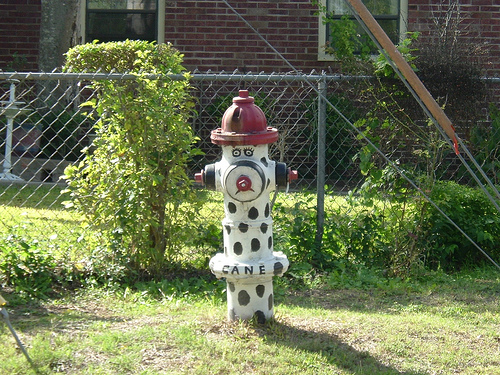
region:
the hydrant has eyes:
[225, 144, 259, 159]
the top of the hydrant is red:
[200, 89, 282, 147]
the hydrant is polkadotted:
[184, 87, 311, 322]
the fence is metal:
[12, 55, 66, 205]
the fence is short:
[7, 49, 82, 225]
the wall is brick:
[181, 25, 241, 59]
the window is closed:
[85, 3, 166, 41]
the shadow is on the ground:
[315, 322, 367, 371]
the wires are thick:
[437, 60, 496, 277]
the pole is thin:
[302, 135, 340, 268]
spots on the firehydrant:
[214, 202, 277, 292]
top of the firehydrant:
[193, 90, 280, 154]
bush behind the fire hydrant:
[30, 87, 203, 309]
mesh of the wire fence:
[273, 101, 309, 174]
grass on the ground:
[96, 323, 203, 368]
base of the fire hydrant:
[205, 287, 293, 342]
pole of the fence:
[290, 95, 340, 264]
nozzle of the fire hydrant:
[265, 157, 305, 225]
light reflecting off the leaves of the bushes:
[26, 207, 96, 274]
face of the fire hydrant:
[206, 100, 277, 233]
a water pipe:
[214, 56, 300, 323]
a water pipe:
[199, 176, 317, 346]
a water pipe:
[180, 90, 280, 345]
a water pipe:
[165, 175, 260, 354]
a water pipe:
[207, 185, 265, 357]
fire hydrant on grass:
[204, 82, 303, 334]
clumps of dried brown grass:
[120, 304, 199, 372]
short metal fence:
[26, 53, 208, 272]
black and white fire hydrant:
[214, 88, 291, 330]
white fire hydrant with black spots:
[217, 149, 276, 306]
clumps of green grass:
[94, 324, 159, 374]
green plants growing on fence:
[314, 232, 414, 298]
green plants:
[0, 267, 58, 300]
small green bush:
[71, 37, 182, 280]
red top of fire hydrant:
[212, 82, 272, 143]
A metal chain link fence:
[2, 62, 448, 248]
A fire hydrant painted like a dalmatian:
[189, 87, 299, 321]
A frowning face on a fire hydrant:
[214, 140, 277, 202]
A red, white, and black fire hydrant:
[191, 85, 299, 325]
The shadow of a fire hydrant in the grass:
[261, 317, 391, 372]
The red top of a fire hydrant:
[203, 87, 288, 145]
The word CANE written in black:
[218, 258, 268, 278]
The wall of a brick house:
[166, 0, 333, 77]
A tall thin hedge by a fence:
[67, 40, 204, 270]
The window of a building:
[312, 1, 417, 63]